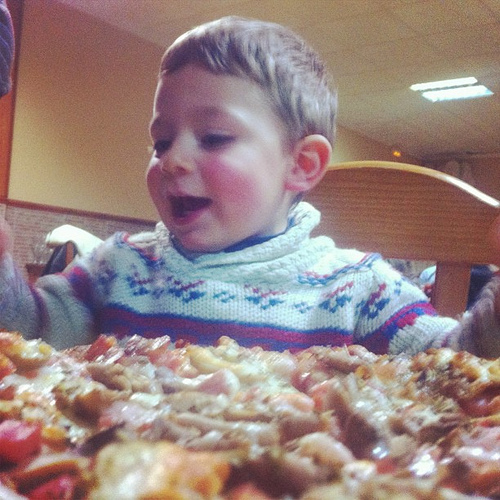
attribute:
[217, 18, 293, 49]
hair — blonde, short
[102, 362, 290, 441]
pizza — here, large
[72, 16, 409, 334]
boy — smiling, here, happy, sitting, young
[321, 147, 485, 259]
chair — wood, red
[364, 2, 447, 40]
ceiling — here, tiled, tile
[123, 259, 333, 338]
sweater — here, white, winter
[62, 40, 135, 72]
wall — here, gray, yellow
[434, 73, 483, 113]
light — yellow, white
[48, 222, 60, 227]
cloth — here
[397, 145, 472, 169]
sign — exit